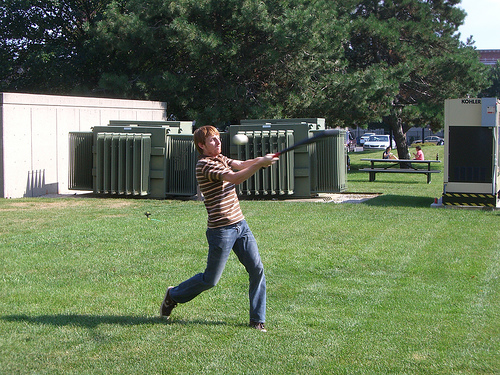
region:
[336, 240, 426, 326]
the grass is short and green.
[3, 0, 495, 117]
a bunch of green trees.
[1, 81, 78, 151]
a white wall.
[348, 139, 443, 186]
a dark green bench.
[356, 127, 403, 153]
a white car is parked.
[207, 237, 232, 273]
a man is wearing jeans.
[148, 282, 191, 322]
a man is wearing burgundy and white sneakers.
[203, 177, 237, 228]
a man is wearing a pleaded brown and pink shirt.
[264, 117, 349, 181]
a man is holding a black bat.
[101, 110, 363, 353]
a man is striking at the ball.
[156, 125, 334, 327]
man hitting a ball with a bat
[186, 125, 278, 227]
man wearing a striped shirt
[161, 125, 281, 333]
man wearing tight jeans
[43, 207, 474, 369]
neatly trimmed grass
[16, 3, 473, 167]
big dark green trees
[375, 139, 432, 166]
people sitting together near a tree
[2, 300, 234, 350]
shadow cast on the ground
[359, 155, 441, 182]
park bench on the grass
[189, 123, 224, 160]
bright orange hair and beard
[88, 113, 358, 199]
grey machinery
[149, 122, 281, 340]
young man wearing striped shirt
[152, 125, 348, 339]
young man swinging at baseball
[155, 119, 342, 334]
young man who swung and missed a baseball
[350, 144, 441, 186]
picnic table in a grassy area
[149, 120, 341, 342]
young man swinging a baseball bat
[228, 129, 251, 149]
white ball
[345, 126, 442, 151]
a few parked cars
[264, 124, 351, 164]
black baseball bat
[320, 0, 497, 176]
large very leafy green tree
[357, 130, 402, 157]
small white car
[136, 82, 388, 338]
man is playing baseball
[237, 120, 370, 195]
the bat is in motion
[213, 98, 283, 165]
the ball is moving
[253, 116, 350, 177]
the bat is black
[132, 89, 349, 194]
man is swinging the bat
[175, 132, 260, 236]
the shirt is striped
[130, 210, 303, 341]
man is wearing jeans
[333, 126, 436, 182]
people sitting in the grass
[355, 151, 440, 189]
an empty bench in the background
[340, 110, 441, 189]
parked car in the distance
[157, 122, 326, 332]
Man swinging a baseball bat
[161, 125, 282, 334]
Man wearing a short sleeved shirt and jeans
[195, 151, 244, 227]
Striped short sleeve shirt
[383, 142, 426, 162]
Two women sitting near a tree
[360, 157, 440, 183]
Empty picnic table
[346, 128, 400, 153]
Cars parked in a parking lot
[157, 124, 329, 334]
Man hitting a baseball with his bat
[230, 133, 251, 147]
White baseball moving through the air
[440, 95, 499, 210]
Large white appliance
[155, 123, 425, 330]
Three people in a park